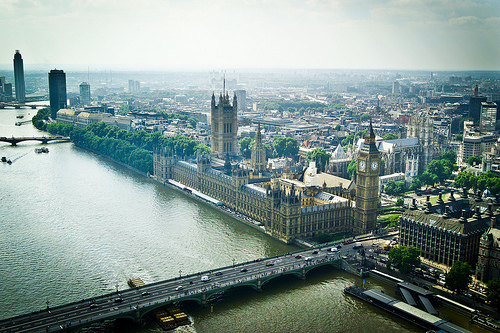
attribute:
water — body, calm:
[0, 107, 428, 330]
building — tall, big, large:
[13, 50, 25, 103]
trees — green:
[47, 116, 213, 182]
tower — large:
[48, 68, 67, 121]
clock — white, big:
[358, 157, 366, 171]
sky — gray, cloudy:
[0, 1, 498, 75]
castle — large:
[154, 77, 382, 243]